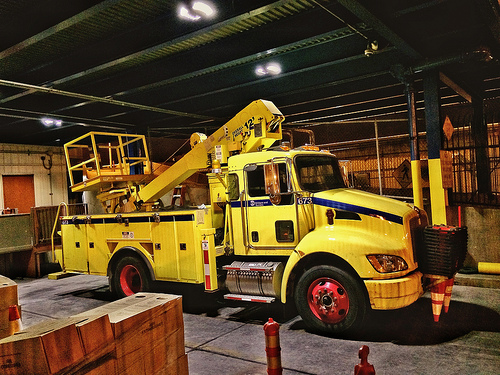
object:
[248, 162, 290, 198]
window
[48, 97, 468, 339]
truck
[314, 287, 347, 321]
rim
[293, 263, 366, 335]
tire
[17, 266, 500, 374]
ground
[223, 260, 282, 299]
item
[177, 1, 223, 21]
light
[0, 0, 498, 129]
roof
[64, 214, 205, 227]
stripe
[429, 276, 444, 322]
cone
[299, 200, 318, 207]
number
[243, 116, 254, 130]
number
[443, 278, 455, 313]
cones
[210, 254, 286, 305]
steps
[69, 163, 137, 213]
bucket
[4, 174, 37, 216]
door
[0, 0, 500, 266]
building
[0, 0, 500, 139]
ceiling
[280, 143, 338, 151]
lights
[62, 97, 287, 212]
lift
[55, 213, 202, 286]
compartments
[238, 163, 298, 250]
door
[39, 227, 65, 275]
step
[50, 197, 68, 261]
rail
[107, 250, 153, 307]
tire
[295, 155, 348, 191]
windshield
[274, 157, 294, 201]
mirror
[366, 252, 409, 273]
headlights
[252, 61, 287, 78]
lights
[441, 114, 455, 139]
sign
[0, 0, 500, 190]
background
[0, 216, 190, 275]
crates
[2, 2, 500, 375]
warehouse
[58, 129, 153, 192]
cage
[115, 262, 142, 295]
hub cap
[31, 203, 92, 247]
fence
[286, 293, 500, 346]
shadow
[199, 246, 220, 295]
reflectors